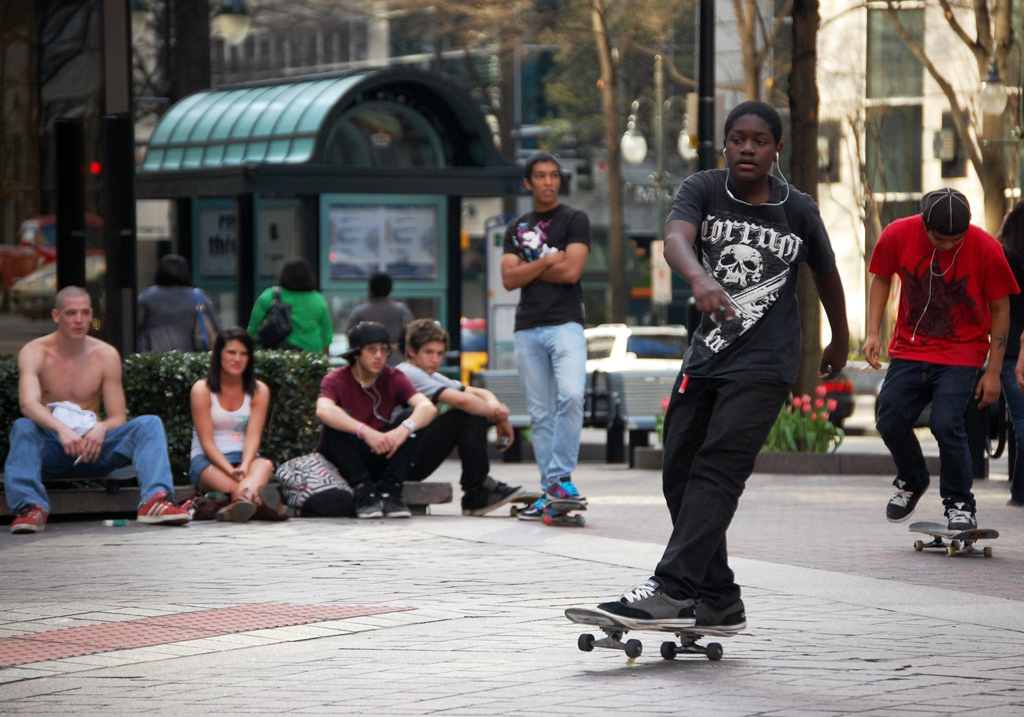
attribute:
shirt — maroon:
[313, 360, 418, 441]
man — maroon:
[311, 317, 442, 521]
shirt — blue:
[390, 360, 467, 430]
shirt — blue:
[385, 362, 468, 438]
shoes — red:
[133, 493, 194, 522]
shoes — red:
[7, 500, 46, 535]